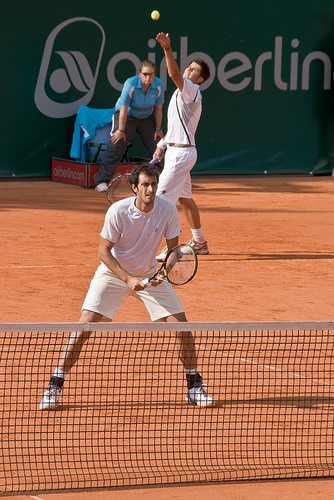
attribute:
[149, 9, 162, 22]
ball — green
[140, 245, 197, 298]
raquet — black, white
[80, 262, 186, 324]
shorts — white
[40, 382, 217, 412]
sneakers — grey, white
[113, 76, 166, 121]
shirt — turquoise, blue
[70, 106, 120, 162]
jacket — blue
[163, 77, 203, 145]
shirt — white, grey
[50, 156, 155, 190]
platform — red, wooden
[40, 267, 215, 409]
legs — apart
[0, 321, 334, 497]
net — separating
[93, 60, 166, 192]
person — leaning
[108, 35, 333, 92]
letters — white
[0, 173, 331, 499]
court — clay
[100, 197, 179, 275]
shirt — white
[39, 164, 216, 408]
player — bend, ready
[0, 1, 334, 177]
poster — visble, green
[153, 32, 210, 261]
man — playing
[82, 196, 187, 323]
clothes — white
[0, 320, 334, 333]
border — white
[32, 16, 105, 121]
logo — white